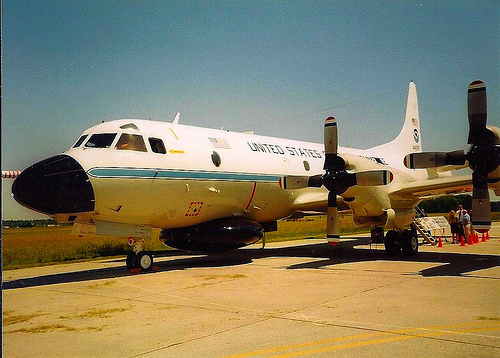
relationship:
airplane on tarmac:
[7, 79, 498, 273] [1, 219, 498, 356]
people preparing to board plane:
[447, 208, 460, 243] [9, 79, 498, 275]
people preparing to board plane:
[456, 203, 464, 223] [9, 79, 498, 275]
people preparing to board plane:
[461, 209, 468, 241] [9, 79, 498, 275]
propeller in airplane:
[275, 116, 393, 249] [7, 79, 498, 273]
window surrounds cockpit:
[114, 131, 146, 151] [64, 109, 183, 214]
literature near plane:
[422, 215, 449, 231] [3, 62, 470, 271]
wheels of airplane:
[124, 251, 158, 274] [22, 80, 482, 260]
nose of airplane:
[23, 150, 90, 209] [20, 58, 445, 263]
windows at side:
[207, 150, 224, 169] [239, 160, 323, 216]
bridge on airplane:
[412, 221, 436, 246] [7, 79, 498, 273]